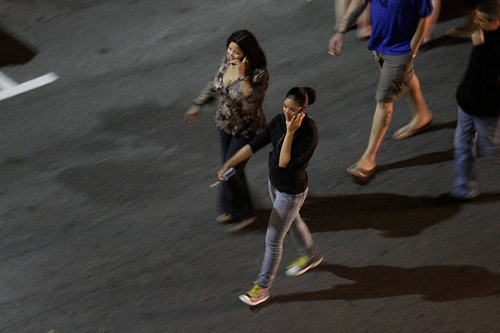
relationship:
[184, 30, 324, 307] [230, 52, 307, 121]
women holding phones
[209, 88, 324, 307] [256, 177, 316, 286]
women wearing jeans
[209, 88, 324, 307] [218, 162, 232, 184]
women has hand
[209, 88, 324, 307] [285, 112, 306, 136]
women has hand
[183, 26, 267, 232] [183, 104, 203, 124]
woman has hand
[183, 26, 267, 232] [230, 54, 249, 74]
woman has hand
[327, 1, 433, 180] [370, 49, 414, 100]
man wearing shorts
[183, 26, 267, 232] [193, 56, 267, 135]
woman wearing blouse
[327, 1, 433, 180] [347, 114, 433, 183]
man wearing sandals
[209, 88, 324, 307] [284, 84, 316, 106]
women has hair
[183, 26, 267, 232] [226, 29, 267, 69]
woman has hair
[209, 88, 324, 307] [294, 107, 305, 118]
women has phone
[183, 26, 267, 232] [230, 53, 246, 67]
woman on phone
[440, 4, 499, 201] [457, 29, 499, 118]
man wearing shirt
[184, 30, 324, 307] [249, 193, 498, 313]
women have shadows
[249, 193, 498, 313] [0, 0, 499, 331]
shadows on road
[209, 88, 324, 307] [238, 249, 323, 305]
women wearing shoes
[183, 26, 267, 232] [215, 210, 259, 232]
woman wearing shoes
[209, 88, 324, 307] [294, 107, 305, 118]
women holding phone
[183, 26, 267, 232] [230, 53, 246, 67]
woman holding phone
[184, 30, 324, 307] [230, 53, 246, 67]
women on phone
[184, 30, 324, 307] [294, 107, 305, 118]
women on phone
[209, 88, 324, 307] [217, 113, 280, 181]
women has arm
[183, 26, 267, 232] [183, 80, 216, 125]
woman has arm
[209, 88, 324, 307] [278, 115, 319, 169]
women has arm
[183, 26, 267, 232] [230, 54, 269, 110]
woman has arm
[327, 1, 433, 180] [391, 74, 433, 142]
man has leg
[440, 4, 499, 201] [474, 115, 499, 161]
man has leg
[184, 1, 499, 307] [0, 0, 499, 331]
people on road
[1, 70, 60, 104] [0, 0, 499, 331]
line on road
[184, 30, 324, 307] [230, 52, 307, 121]
women on phones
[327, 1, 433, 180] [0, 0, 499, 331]
man on road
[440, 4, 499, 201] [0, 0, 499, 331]
man on road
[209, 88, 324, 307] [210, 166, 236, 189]
women holding purse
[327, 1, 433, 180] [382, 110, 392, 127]
man has tattoo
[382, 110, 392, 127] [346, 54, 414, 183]
tattoo on leg